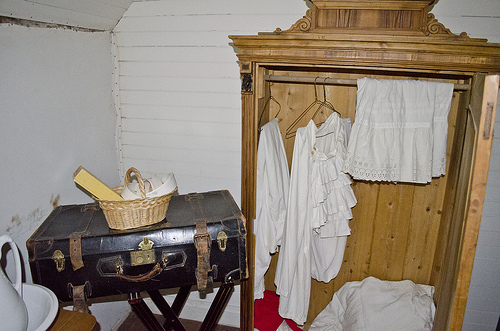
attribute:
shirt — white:
[272, 113, 358, 325]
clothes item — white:
[274, 111, 360, 325]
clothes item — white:
[342, 72, 455, 185]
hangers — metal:
[255, 77, 340, 141]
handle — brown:
[111, 263, 161, 283]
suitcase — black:
[27, 190, 249, 302]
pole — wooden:
[245, 68, 482, 104]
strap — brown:
[61, 214, 88, 274]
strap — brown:
[183, 196, 220, 293]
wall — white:
[112, 0, 311, 195]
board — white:
[114, 12, 171, 63]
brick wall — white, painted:
[114, 0, 499, 330]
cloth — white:
[343, 68, 455, 190]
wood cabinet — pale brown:
[223, 18, 468, 295]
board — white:
[116, 43, 240, 62]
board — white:
[471, 290, 493, 326]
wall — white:
[470, 247, 497, 307]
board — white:
[122, 116, 239, 140]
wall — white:
[108, 0, 497, 329]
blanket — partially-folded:
[314, 270, 441, 329]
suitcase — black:
[29, 195, 248, 292]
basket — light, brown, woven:
[96, 167, 176, 229]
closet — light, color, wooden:
[232, 0, 490, 330]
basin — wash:
[1, 231, 62, 329]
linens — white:
[233, 85, 455, 318]